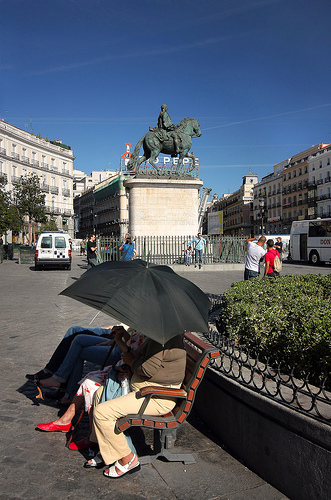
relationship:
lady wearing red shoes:
[34, 332, 147, 451] [34, 420, 72, 431]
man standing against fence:
[186, 231, 207, 267] [93, 233, 250, 263]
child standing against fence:
[181, 246, 193, 266] [93, 233, 250, 263]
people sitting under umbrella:
[26, 321, 184, 476] [59, 258, 211, 345]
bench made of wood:
[115, 336, 213, 466] [190, 346, 210, 379]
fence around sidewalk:
[202, 291, 330, 425] [3, 242, 289, 498]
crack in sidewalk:
[234, 479, 256, 492] [9, 263, 41, 311]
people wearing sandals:
[25, 321, 187, 479] [97, 450, 142, 478]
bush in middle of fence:
[214, 271, 330, 376] [182, 292, 330, 424]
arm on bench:
[136, 386, 186, 414] [115, 330, 220, 466]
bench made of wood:
[115, 330, 220, 466] [186, 369, 203, 408]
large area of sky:
[114, 21, 314, 101] [116, 12, 282, 119]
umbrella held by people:
[44, 234, 227, 349] [25, 321, 187, 479]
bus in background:
[289, 216, 330, 264] [14, 99, 311, 273]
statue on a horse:
[126, 102, 201, 181] [119, 117, 206, 174]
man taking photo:
[238, 232, 267, 278] [94, 322, 134, 359]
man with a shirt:
[263, 238, 280, 274] [262, 249, 282, 271]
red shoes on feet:
[33, 419, 88, 450] [37, 411, 74, 439]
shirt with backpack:
[264, 246, 280, 273] [274, 254, 281, 272]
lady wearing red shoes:
[37, 328, 150, 451] [37, 417, 89, 451]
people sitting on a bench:
[26, 321, 184, 476] [82, 225, 270, 280]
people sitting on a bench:
[25, 321, 187, 479] [115, 330, 220, 466]